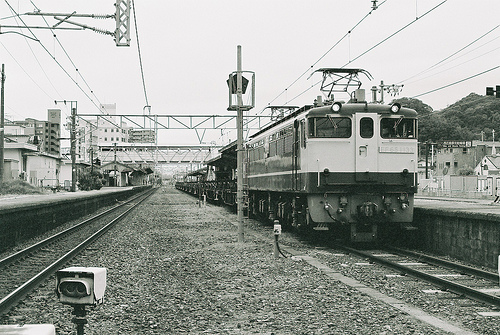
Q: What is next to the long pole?
A: A train.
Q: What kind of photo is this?
A: A black and white photo.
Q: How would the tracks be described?
A: Long and narrow.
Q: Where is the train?
A: At a train station.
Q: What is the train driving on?
A: Train tracks.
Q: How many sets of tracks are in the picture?
A: 2.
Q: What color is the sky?
A: White.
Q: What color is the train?
A: Black and white.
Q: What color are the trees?
A: Green.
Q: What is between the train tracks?
A: Gravel.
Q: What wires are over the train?
A: Power lines.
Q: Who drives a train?
A: Conductor.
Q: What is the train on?
A: Tracks.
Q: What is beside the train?
A: Tracks and sidewalk.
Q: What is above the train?
A: Cable lines.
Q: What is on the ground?
A: Gray gravel.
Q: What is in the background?
A: Buildings and sidewalk.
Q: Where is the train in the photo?
A: On the right.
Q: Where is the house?
A: On the right.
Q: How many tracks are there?
A: 4.